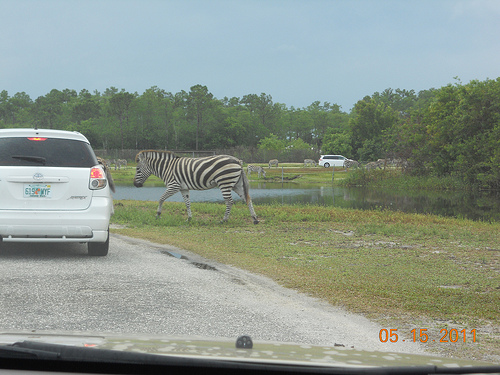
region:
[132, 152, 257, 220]
zebra walking to road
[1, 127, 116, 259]
vehicle on road by zebra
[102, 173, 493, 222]
still water by grass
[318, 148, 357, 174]
white vehicle by animal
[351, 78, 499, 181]
green tree by water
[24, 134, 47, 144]
red light of car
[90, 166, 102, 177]
red light of car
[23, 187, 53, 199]
white plates of car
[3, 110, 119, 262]
white car on the road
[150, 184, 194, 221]
front feet of zebra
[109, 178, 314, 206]
a body of water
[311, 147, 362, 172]
a white car in front trees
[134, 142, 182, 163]
mane of zebra is white and black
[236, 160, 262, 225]
tail of zebra is long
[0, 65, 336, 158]
trees on the background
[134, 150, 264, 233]
The zebra walking.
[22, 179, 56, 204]
The license plate.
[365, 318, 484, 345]
The date in orange.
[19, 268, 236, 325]
The road.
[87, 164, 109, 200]
The light on the back of the car.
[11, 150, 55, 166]
The windshield wiper.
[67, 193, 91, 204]
Writing on the car.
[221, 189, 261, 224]
The zebras back legs.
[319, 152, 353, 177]
The white van across the lake.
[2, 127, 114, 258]
The back of a white car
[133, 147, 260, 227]
A zebra by a road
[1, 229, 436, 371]
A gravel road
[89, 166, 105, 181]
A red brake light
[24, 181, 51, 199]
A license plate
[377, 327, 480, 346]
An orange time stamp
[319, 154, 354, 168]
A white vehicle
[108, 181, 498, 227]
A small body of water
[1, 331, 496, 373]
The hood of a car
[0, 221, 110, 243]
A white car bumper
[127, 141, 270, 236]
black and white striped zebra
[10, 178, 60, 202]
white florida license plate with green writing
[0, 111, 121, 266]
white van next to a zebra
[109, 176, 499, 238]
small body of reflective water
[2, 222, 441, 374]
light grey gravel covered road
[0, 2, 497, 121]
hazy light bluesky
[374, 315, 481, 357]
date displayed in orange digital numbers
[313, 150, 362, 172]
white van